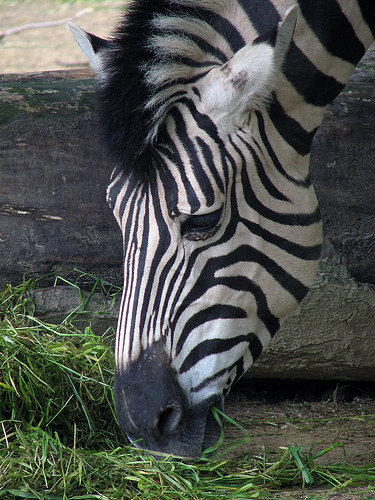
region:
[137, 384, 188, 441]
Nose of a zebra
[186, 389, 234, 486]
Mouth of a zebra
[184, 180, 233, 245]
Eye of a zebra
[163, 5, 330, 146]
Ear of a zebra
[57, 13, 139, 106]
Ear of a zebra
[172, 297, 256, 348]
Black stripe of a zebra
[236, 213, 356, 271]
Black stripe of a zebra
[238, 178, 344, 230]
Black stripe of a zebra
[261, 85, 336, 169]
Black stripe of a zebra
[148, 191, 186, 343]
Black stripe of a zebra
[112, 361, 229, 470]
zebra has black nose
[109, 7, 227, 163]
zebra has black and white mane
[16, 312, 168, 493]
zebra is eating grass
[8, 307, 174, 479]
green grass next to zebra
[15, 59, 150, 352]
dark grey wooden stump near zebra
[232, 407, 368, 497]
grass on brown ground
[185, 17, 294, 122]
mostly white ears on zebra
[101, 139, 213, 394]
narrow stripes on zebra's face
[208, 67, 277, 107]
white hair on zebra's ears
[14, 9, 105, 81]
light grey ground in back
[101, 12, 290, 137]
black and white hair on zebra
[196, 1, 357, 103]
zebra has white ears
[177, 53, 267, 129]
white hair on ears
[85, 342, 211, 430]
zebra has dark nose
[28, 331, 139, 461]
zebra eats green grass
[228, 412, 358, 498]
brown ground near green grass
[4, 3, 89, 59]
white ground behind zebra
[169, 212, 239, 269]
zebra has black eyes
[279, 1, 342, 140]
thick stripes on zebra's neck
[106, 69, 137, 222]
black hair near zebra's eyes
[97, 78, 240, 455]
zebra is eating grass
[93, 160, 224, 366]
narrow white stripes on zebra's face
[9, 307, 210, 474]
green grass on ground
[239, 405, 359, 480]
ground near grass is brown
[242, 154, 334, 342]
white and black stripes on zebra's face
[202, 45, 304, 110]
white hair on zebra's ears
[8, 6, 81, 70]
light brown grass in background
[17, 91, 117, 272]
green and grey rock near zebra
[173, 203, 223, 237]
the eye on the zebra's head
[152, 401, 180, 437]
the nostril on the zebras head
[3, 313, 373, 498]
the green grass on the ground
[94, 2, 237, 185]
the mane on the zebra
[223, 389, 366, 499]
the dirt on the ground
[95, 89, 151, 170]
the black hair on the zebra's mane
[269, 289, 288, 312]
the white spot on the zebra's head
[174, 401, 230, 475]
the mouth on the zebra's head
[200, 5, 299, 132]
the left ear on the zebra's head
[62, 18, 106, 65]
the right ear on the zebra's head